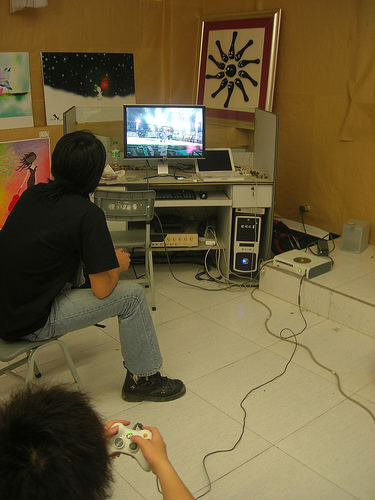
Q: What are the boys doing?
A: Playing video games.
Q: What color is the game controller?
A: White.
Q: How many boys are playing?
A: Two.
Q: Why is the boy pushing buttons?
A: To control the game.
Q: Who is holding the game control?
A: The boy sitting further from the screen.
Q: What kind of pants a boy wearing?
A: Jeans.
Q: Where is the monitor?
A: On a desk.